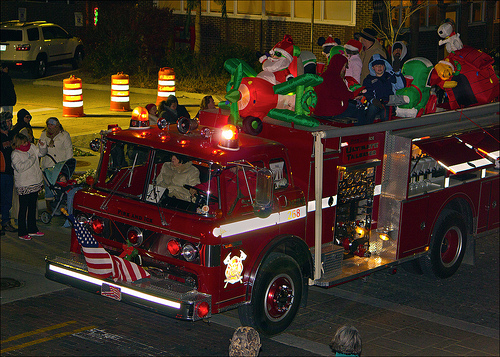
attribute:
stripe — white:
[214, 150, 484, 236]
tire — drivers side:
[242, 245, 311, 339]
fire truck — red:
[34, 89, 490, 352]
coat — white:
[0, 143, 52, 197]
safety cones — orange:
[20, 314, 95, 350]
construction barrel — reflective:
[37, 58, 206, 133]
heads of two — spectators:
[218, 305, 383, 355]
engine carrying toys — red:
[204, 18, 497, 126]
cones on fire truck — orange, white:
[38, 66, 189, 124]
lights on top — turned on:
[121, 95, 268, 170]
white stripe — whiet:
[204, 136, 496, 254]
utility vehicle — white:
[2, 18, 96, 69]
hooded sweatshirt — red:
[301, 44, 397, 135]